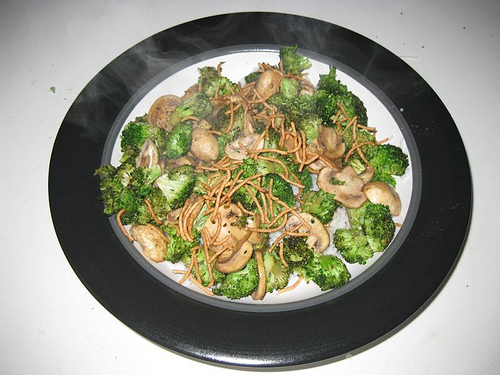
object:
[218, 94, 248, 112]
mushroom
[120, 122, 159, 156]
broccoli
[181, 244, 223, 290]
noodles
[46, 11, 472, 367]
dish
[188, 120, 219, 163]
mushroom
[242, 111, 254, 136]
mushroom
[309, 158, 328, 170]
mushroom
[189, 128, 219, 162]
mushroom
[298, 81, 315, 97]
mushroom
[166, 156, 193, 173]
mushroom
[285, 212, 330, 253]
mushroom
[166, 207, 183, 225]
mushroom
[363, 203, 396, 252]
broccoli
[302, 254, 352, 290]
broccoli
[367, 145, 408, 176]
broccoli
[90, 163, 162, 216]
broccoli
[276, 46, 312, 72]
broccoli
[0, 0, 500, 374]
table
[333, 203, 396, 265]
vegetables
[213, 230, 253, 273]
mushroom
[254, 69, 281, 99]
mushroom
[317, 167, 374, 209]
mushroom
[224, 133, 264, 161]
mushroom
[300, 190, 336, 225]
broccoli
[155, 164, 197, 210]
broccoli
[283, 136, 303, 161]
mushroom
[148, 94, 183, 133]
mushroom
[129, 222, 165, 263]
mushroom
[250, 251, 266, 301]
mushroom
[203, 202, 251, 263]
mushroom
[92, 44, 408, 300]
stir fry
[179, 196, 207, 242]
noodles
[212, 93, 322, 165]
noodles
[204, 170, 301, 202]
noodles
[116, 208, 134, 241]
noodles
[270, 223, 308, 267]
noodles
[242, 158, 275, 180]
broccoli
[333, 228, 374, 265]
broccoli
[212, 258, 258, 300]
broccoli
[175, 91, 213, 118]
broccoli